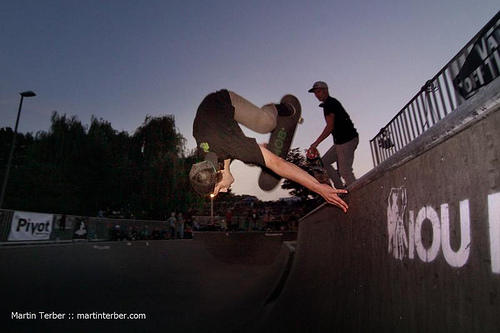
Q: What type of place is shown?
A: It is a park.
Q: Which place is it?
A: It is a park.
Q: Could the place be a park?
A: Yes, it is a park.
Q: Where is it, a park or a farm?
A: It is a park.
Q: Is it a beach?
A: No, it is a park.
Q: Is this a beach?
A: No, it is a park.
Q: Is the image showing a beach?
A: No, the picture is showing a park.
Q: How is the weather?
A: It is clear.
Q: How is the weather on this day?
A: It is clear.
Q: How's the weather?
A: It is clear.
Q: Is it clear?
A: Yes, it is clear.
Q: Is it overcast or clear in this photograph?
A: It is clear.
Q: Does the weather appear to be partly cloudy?
A: No, it is clear.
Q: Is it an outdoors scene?
A: Yes, it is outdoors.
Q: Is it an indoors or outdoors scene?
A: It is outdoors.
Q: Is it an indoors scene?
A: No, it is outdoors.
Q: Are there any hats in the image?
A: Yes, there is a hat.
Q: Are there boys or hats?
A: Yes, there is a hat.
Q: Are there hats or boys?
A: Yes, there is a hat.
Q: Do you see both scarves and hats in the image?
A: No, there is a hat but no scarves.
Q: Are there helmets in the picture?
A: No, there are no helmets.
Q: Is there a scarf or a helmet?
A: No, there are no helmets or scarves.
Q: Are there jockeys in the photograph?
A: No, there are no jockeys.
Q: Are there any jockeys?
A: No, there are no jockeys.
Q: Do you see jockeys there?
A: No, there are no jockeys.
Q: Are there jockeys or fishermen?
A: No, there are no jockeys or fishermen.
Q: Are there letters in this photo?
A: Yes, there are letters.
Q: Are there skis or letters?
A: Yes, there are letters.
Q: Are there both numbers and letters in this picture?
A: No, there are letters but no numbers.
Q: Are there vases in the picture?
A: No, there are no vases.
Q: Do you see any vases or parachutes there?
A: No, there are no vases or parachutes.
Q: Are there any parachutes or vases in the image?
A: No, there are no vases or parachutes.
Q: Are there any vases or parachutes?
A: No, there are no vases or parachutes.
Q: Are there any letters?
A: Yes, there are letters.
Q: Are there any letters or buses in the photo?
A: Yes, there are letters.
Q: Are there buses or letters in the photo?
A: Yes, there are letters.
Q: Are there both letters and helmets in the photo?
A: No, there are letters but no helmets.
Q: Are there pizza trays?
A: No, there are no pizza trays.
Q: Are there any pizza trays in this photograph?
A: No, there are no pizza trays.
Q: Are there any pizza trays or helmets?
A: No, there are no pizza trays or helmets.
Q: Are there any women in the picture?
A: No, there are no women.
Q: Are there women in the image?
A: No, there are no women.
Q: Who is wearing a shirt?
A: The boy is wearing a shirt.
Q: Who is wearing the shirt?
A: The boy is wearing a shirt.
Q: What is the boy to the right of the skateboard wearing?
A: The boy is wearing a shirt.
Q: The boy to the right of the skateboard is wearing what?
A: The boy is wearing a shirt.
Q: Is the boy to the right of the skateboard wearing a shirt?
A: Yes, the boy is wearing a shirt.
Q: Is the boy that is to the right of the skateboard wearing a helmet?
A: No, the boy is wearing a shirt.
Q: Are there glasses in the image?
A: No, there are no glasses.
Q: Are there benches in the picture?
A: No, there are no benches.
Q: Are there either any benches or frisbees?
A: No, there are no benches or frisbees.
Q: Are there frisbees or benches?
A: No, there are no benches or frisbees.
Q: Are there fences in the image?
A: Yes, there is a fence.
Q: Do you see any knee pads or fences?
A: Yes, there is a fence.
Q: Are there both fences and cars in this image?
A: No, there is a fence but no cars.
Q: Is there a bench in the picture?
A: No, there are no benches.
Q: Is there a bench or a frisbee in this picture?
A: No, there are no benches or frisbees.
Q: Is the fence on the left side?
A: Yes, the fence is on the left of the image.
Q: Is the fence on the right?
A: No, the fence is on the left of the image.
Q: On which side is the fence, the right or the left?
A: The fence is on the left of the image.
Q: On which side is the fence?
A: The fence is on the left of the image.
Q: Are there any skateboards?
A: Yes, there is a skateboard.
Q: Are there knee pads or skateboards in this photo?
A: Yes, there is a skateboard.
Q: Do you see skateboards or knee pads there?
A: Yes, there is a skateboard.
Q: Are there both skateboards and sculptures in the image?
A: No, there is a skateboard but no sculptures.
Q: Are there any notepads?
A: No, there are no notepads.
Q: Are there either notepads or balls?
A: No, there are no notepads or balls.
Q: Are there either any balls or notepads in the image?
A: No, there are no notepads or balls.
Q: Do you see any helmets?
A: No, there are no helmets.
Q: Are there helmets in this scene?
A: No, there are no helmets.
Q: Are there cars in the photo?
A: No, there are no cars.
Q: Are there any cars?
A: No, there are no cars.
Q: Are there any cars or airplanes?
A: No, there are no cars or airplanes.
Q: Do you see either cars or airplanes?
A: No, there are no cars or airplanes.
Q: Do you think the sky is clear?
A: Yes, the sky is clear.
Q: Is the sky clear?
A: Yes, the sky is clear.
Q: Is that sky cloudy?
A: No, the sky is clear.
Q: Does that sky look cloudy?
A: No, the sky is clear.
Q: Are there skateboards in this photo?
A: Yes, there is a skateboard.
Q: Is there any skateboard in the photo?
A: Yes, there is a skateboard.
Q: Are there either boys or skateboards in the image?
A: Yes, there is a skateboard.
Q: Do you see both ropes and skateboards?
A: No, there is a skateboard but no ropes.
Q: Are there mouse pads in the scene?
A: No, there are no mouse pads.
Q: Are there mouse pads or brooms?
A: No, there are no mouse pads or brooms.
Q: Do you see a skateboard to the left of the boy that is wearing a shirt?
A: Yes, there is a skateboard to the left of the boy.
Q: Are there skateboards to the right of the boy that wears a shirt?
A: No, the skateboard is to the left of the boy.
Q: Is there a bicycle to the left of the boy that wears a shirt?
A: No, there is a skateboard to the left of the boy.